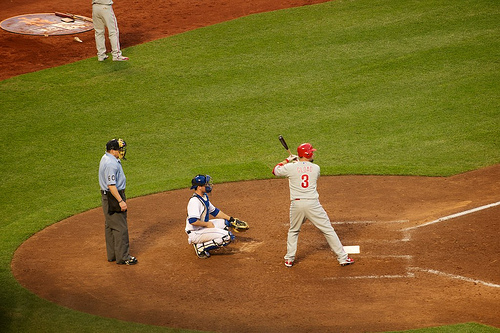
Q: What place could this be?
A: It is a field.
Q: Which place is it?
A: It is a field.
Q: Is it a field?
A: Yes, it is a field.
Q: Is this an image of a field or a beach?
A: It is showing a field.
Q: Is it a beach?
A: No, it is a field.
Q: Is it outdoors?
A: Yes, it is outdoors.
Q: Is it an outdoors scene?
A: Yes, it is outdoors.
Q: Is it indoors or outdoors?
A: It is outdoors.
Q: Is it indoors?
A: No, it is outdoors.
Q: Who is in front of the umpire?
A: The catcher is in front of the umpire.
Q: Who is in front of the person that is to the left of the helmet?
A: The catcher is in front of the umpire.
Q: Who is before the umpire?
A: The catcher is in front of the umpire.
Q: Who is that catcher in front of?
A: The catcher is in front of the umpire.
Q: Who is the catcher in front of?
A: The catcher is in front of the umpire.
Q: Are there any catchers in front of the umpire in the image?
A: Yes, there is a catcher in front of the umpire.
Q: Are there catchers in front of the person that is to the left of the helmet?
A: Yes, there is a catcher in front of the umpire.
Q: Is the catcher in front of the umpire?
A: Yes, the catcher is in front of the umpire.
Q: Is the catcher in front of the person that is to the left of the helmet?
A: Yes, the catcher is in front of the umpire.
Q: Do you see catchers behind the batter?
A: Yes, there is a catcher behind the batter.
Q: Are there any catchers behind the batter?
A: Yes, there is a catcher behind the batter.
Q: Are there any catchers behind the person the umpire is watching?
A: Yes, there is a catcher behind the batter.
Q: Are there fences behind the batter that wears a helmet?
A: No, there is a catcher behind the batter.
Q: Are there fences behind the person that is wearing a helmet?
A: No, there is a catcher behind the batter.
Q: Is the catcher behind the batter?
A: Yes, the catcher is behind the batter.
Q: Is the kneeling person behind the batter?
A: Yes, the catcher is behind the batter.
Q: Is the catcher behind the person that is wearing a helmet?
A: Yes, the catcher is behind the batter.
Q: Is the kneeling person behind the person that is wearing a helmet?
A: Yes, the catcher is behind the batter.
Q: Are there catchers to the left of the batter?
A: Yes, there is a catcher to the left of the batter.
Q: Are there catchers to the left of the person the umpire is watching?
A: Yes, there is a catcher to the left of the batter.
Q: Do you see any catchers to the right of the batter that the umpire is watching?
A: No, the catcher is to the left of the batter.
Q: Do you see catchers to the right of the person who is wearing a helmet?
A: No, the catcher is to the left of the batter.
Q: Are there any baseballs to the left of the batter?
A: No, there is a catcher to the left of the batter.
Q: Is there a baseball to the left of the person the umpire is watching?
A: No, there is a catcher to the left of the batter.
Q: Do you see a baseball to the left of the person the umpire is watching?
A: No, there is a catcher to the left of the batter.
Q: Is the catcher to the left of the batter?
A: Yes, the catcher is to the left of the batter.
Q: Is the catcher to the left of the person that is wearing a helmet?
A: Yes, the catcher is to the left of the batter.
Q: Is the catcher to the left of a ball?
A: No, the catcher is to the left of the batter.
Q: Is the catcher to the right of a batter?
A: No, the catcher is to the left of a batter.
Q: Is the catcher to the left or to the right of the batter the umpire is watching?
A: The catcher is to the left of the batter.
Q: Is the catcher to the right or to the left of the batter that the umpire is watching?
A: The catcher is to the left of the batter.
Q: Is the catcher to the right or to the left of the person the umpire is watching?
A: The catcher is to the left of the batter.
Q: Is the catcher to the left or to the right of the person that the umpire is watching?
A: The catcher is to the left of the batter.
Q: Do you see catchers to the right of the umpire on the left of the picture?
A: Yes, there is a catcher to the right of the umpire.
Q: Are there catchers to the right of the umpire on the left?
A: Yes, there is a catcher to the right of the umpire.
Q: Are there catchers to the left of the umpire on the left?
A: No, the catcher is to the right of the umpire.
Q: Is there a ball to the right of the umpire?
A: No, there is a catcher to the right of the umpire.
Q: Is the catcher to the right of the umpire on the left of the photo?
A: Yes, the catcher is to the right of the umpire.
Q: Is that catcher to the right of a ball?
A: No, the catcher is to the right of the umpire.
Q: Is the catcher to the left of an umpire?
A: No, the catcher is to the right of an umpire.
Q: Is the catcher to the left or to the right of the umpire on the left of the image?
A: The catcher is to the right of the umpire.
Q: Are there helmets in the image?
A: Yes, there is a helmet.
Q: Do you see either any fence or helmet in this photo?
A: Yes, there is a helmet.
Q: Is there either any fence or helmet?
A: Yes, there is a helmet.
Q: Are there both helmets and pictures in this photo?
A: No, there is a helmet but no pictures.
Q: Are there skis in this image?
A: No, there are no skis.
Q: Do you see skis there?
A: No, there are no skis.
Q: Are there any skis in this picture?
A: No, there are no skis.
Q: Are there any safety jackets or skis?
A: No, there are no skis or safety jackets.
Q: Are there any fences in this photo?
A: No, there are no fences.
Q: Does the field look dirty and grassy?
A: Yes, the field is dirty and grassy.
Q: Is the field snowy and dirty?
A: No, the field is dirty but grassy.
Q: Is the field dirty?
A: Yes, the field is dirty.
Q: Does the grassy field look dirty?
A: Yes, the field is dirty.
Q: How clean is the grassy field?
A: The field is dirty.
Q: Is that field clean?
A: No, the field is dirty.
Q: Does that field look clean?
A: No, the field is dirty.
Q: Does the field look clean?
A: No, the field is dirty.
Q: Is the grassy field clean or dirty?
A: The field is dirty.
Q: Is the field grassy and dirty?
A: Yes, the field is grassy and dirty.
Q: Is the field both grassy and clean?
A: No, the field is grassy but dirty.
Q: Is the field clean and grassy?
A: No, the field is grassy but dirty.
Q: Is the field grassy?
A: Yes, the field is grassy.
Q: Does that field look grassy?
A: Yes, the field is grassy.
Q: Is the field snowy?
A: No, the field is grassy.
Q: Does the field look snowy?
A: No, the field is grassy.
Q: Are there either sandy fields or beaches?
A: No, there is a field but it is grassy.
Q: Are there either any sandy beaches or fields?
A: No, there is a field but it is grassy.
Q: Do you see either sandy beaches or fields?
A: No, there is a field but it is grassy.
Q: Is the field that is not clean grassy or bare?
A: The field is grassy.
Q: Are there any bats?
A: Yes, there is a bat.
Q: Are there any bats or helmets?
A: Yes, there is a bat.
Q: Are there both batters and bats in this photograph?
A: Yes, there are both a bat and a batter.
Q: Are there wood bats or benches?
A: Yes, there is a wood bat.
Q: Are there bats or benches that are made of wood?
A: Yes, the bat is made of wood.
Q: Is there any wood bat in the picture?
A: Yes, there is a wood bat.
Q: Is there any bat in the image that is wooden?
A: Yes, there is a bat that is wooden.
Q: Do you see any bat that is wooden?
A: Yes, there is a bat that is wooden.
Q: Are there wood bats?
A: Yes, there is a bat that is made of wood.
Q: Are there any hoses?
A: No, there are no hoses.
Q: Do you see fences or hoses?
A: No, there are no hoses or fences.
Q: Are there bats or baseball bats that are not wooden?
A: No, there is a bat but it is wooden.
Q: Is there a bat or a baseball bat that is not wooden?
A: No, there is a bat but it is wooden.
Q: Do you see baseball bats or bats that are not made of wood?
A: No, there is a bat but it is made of wood.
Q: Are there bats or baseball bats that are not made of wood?
A: No, there is a bat but it is made of wood.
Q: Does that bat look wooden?
A: Yes, the bat is wooden.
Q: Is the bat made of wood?
A: Yes, the bat is made of wood.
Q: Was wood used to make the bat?
A: Yes, the bat is made of wood.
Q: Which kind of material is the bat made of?
A: The bat is made of wood.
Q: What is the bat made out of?
A: The bat is made of wood.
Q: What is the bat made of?
A: The bat is made of wood.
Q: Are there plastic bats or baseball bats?
A: No, there is a bat but it is wooden.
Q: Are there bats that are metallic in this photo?
A: No, there is a bat but it is wooden.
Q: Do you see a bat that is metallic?
A: No, there is a bat but it is wooden.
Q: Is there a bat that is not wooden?
A: No, there is a bat but it is wooden.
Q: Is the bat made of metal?
A: No, the bat is made of wood.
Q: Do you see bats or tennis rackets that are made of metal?
A: No, there is a bat but it is made of wood.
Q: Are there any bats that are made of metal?
A: No, there is a bat but it is made of wood.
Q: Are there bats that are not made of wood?
A: No, there is a bat but it is made of wood.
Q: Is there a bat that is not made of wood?
A: No, there is a bat but it is made of wood.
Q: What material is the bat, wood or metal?
A: The bat is made of wood.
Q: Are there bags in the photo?
A: No, there are no bags.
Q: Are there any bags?
A: No, there are no bags.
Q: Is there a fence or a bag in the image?
A: No, there are no bags or fences.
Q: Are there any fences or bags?
A: No, there are no bags or fences.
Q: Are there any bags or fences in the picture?
A: No, there are no bags or fences.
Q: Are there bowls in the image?
A: No, there are no bowls.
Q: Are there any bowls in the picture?
A: No, there are no bowls.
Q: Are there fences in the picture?
A: No, there are no fences.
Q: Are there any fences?
A: No, there are no fences.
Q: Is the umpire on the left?
A: Yes, the umpire is on the left of the image.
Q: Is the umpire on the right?
A: No, the umpire is on the left of the image.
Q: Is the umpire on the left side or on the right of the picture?
A: The umpire is on the left of the image.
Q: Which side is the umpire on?
A: The umpire is on the left of the image.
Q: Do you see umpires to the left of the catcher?
A: Yes, there is an umpire to the left of the catcher.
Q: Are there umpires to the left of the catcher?
A: Yes, there is an umpire to the left of the catcher.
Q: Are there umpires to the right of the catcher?
A: No, the umpire is to the left of the catcher.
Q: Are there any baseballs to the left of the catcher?
A: No, there is an umpire to the left of the catcher.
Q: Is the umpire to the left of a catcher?
A: Yes, the umpire is to the left of a catcher.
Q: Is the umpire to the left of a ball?
A: No, the umpire is to the left of a catcher.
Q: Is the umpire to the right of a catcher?
A: No, the umpire is to the left of a catcher.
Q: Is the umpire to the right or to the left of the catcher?
A: The umpire is to the left of the catcher.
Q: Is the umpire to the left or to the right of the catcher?
A: The umpire is to the left of the catcher.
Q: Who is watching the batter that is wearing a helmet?
A: The umpire is watching the batter.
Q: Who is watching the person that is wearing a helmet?
A: The umpire is watching the batter.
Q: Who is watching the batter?
A: The umpire is watching the batter.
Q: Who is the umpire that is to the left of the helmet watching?
A: The umpire is watching the batter.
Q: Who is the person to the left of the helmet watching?
A: The umpire is watching the batter.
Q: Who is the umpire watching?
A: The umpire is watching the batter.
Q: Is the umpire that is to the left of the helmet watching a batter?
A: Yes, the umpire is watching a batter.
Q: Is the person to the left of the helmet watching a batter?
A: Yes, the umpire is watching a batter.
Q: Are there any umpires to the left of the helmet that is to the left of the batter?
A: Yes, there is an umpire to the left of the helmet.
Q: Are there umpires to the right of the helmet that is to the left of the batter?
A: No, the umpire is to the left of the helmet.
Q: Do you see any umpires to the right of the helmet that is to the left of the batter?
A: No, the umpire is to the left of the helmet.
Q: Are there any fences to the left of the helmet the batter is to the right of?
A: No, there is an umpire to the left of the helmet.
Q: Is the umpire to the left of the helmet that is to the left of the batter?
A: Yes, the umpire is to the left of the helmet.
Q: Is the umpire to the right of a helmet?
A: No, the umpire is to the left of a helmet.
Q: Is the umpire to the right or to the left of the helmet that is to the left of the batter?
A: The umpire is to the left of the helmet.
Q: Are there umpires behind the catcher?
A: Yes, there is an umpire behind the catcher.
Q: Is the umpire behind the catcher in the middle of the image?
A: Yes, the umpire is behind the catcher.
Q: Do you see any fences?
A: No, there are no fences.